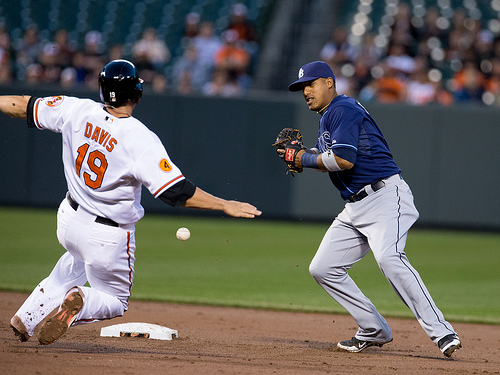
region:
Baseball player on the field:
[259, 50, 456, 357]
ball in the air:
[173, 225, 200, 252]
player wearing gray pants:
[321, 172, 436, 339]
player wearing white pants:
[24, 190, 131, 340]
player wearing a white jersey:
[20, 80, 168, 222]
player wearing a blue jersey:
[301, 105, 406, 199]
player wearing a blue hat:
[278, 58, 337, 93]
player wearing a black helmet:
[84, 49, 162, 109]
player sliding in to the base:
[33, 106, 193, 372]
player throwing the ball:
[265, 47, 443, 371]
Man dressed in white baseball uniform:
[5, 37, 266, 370]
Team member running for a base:
[2, 27, 271, 363]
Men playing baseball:
[0, 30, 480, 370]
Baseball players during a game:
[3, 28, 493, 363]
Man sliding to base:
[0, 41, 272, 371]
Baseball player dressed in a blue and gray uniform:
[268, 43, 476, 371]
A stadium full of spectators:
[0, 2, 497, 129]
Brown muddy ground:
[53, 316, 330, 368]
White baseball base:
[95, 320, 197, 360]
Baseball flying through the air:
[167, 217, 224, 273]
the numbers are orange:
[72, 155, 108, 177]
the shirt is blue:
[341, 117, 365, 135]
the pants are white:
[94, 235, 113, 257]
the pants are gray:
[371, 207, 388, 238]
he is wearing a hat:
[292, 61, 329, 90]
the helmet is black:
[108, 73, 130, 93]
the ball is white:
[170, 223, 195, 244]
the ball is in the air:
[170, 224, 192, 247]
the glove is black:
[280, 134, 294, 154]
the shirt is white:
[53, 113, 80, 138]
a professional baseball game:
[13, 20, 479, 354]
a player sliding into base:
[3, 45, 274, 354]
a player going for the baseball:
[253, 53, 486, 363]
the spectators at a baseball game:
[19, 28, 496, 88]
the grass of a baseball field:
[10, 215, 497, 312]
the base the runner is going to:
[98, 315, 179, 351]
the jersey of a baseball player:
[27, 92, 201, 226]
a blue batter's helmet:
[90, 48, 145, 115]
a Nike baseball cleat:
[324, 324, 403, 361]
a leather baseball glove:
[270, 120, 307, 182]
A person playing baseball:
[271, 56, 466, 362]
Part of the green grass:
[257, 270, 269, 292]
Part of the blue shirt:
[341, 121, 348, 131]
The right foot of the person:
[336, 325, 397, 355]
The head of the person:
[286, 57, 339, 114]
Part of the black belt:
[376, 182, 383, 188]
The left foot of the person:
[430, 328, 463, 358]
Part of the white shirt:
[127, 142, 146, 162]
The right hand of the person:
[221, 195, 265, 220]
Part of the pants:
[102, 268, 117, 286]